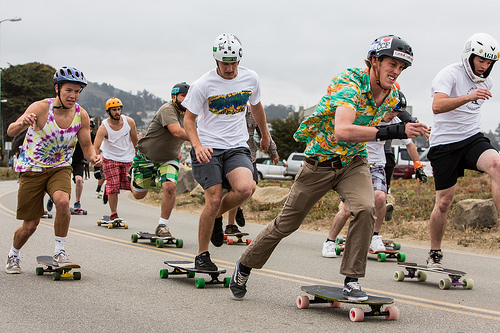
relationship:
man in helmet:
[4, 63, 104, 275] [50, 63, 90, 91]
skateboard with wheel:
[294, 282, 402, 324] [295, 292, 313, 311]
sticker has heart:
[374, 36, 395, 54] [382, 36, 390, 43]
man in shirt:
[230, 27, 431, 304] [291, 66, 401, 170]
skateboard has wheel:
[222, 225, 254, 248] [226, 236, 235, 247]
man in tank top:
[4, 63, 104, 275] [12, 96, 86, 175]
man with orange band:
[320, 89, 426, 265] [410, 156, 424, 171]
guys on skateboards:
[5, 32, 499, 303] [21, 191, 476, 322]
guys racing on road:
[5, 32, 499, 303] [1, 173, 499, 332]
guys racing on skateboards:
[5, 32, 499, 303] [21, 191, 476, 322]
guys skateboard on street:
[5, 32, 499, 303] [1, 173, 499, 332]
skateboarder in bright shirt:
[230, 27, 431, 304] [291, 66, 401, 170]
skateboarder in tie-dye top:
[4, 63, 104, 275] [12, 96, 86, 175]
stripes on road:
[0, 183, 500, 323] [1, 173, 499, 332]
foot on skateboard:
[191, 248, 222, 272] [159, 258, 234, 290]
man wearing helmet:
[4, 63, 104, 275] [50, 63, 90, 91]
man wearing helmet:
[424, 31, 499, 271] [461, 29, 499, 85]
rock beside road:
[248, 180, 295, 212] [1, 173, 499, 332]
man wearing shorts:
[127, 76, 190, 241] [127, 145, 179, 193]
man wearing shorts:
[424, 31, 499, 271] [427, 132, 497, 191]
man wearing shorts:
[4, 63, 104, 275] [15, 165, 74, 222]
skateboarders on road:
[5, 32, 499, 303] [1, 173, 499, 332]